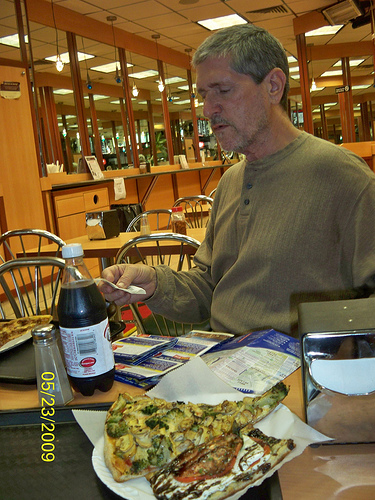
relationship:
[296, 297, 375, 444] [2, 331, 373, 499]
napkin dispenser on table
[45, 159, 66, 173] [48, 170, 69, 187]
straws in box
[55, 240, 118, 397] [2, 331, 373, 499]
bottle of soda on table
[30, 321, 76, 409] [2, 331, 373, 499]
pepper shaker on table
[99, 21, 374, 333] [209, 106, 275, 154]
man has beard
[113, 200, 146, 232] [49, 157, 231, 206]
trash can under counter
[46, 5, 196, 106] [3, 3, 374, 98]
lights hanging from ceiling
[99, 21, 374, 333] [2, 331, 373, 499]
man sitting at table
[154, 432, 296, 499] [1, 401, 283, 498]
pizza on food tray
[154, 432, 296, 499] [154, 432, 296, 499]
pizza on top of pizza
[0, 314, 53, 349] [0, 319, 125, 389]
pizza on food tray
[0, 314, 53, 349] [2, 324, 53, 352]
pizza on paper plate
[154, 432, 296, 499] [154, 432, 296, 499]
pizza under pizza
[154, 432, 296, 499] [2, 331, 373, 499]
pizza on table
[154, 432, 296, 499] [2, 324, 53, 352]
pizza on paper plate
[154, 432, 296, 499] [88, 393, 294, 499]
pizza on paper plate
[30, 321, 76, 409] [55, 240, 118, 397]
pepper shaker next to bottle of soda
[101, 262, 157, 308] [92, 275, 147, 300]
hand holding napkin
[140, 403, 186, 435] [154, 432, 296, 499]
vegetables on pizza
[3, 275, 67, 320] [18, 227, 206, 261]
floor next to table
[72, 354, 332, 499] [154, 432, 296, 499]
paper under pizza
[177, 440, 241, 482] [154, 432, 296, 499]
tomato on pizza